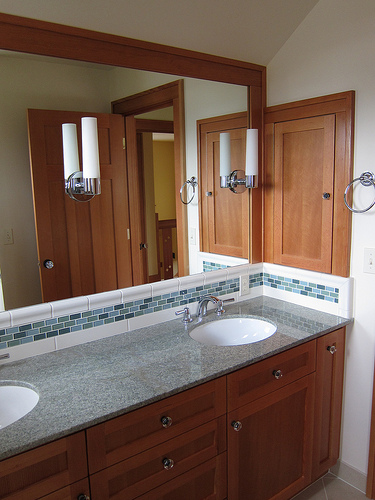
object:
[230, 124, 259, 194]
wall sconces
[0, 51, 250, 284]
mirror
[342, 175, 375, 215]
towel ring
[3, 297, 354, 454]
vanity top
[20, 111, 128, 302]
door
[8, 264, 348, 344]
tile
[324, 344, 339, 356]
knobs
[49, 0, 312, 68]
ceiling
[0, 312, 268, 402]
counter top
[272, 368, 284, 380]
knob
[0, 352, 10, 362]
outlet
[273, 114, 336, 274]
cabinet door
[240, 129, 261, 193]
light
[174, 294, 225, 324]
faucet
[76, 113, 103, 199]
light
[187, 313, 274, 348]
sink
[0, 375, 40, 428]
sink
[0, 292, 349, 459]
counter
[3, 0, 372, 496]
bathroom